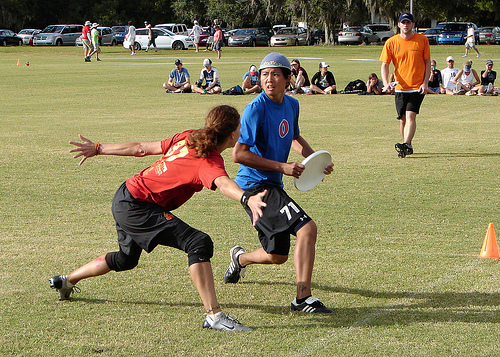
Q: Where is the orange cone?
A: On the right.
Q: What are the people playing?
A: Frisbee.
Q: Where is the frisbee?
A: In the man's hands.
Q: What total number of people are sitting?
A: Ten.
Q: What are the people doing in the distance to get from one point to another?
A: Walking.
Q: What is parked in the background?
A: Cars.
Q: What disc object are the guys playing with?
A: Frisbee.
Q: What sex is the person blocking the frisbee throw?
A: Female.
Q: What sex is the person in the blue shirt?
A: Male.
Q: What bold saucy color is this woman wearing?
A: Red.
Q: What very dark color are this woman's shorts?
A: Black.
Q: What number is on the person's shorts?
A: 71.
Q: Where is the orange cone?
A: Side of the field.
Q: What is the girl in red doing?
A: Blocking.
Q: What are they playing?
A: Frisbee.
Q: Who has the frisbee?
A: The boy in blue.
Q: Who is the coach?
A: The man in orange.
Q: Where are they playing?
A: In a field.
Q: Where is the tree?
A: In front of the vehicles.